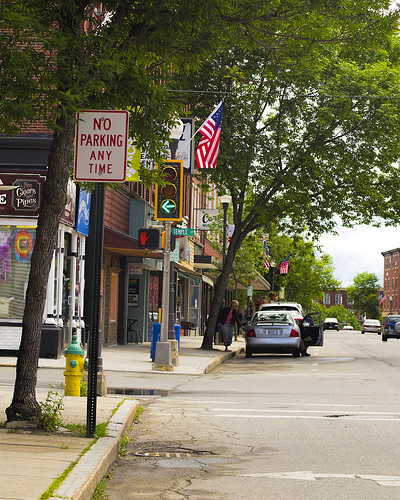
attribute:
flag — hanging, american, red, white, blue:
[194, 102, 228, 174]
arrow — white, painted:
[244, 461, 398, 498]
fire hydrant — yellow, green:
[61, 333, 87, 398]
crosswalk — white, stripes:
[151, 396, 399, 424]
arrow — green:
[162, 200, 178, 218]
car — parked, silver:
[245, 308, 339, 362]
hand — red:
[139, 230, 151, 249]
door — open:
[299, 308, 326, 349]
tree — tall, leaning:
[192, 0, 399, 342]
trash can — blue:
[148, 317, 185, 366]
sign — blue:
[76, 187, 95, 238]